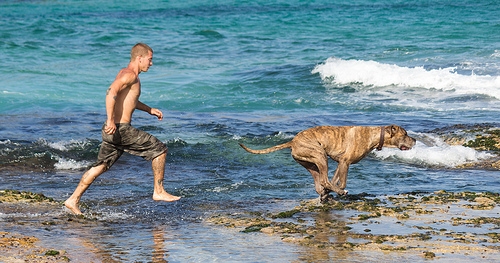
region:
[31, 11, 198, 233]
a man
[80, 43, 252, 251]
a man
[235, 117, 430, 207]
A brindle colored dog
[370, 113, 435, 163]
A dog with a brown collar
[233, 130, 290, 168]
A dog's tail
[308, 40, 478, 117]
An ocean wave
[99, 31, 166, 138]
A shirtless man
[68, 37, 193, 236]
A man running on the water's edge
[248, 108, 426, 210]
A dog running in water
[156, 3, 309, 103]
Blue-green ocean water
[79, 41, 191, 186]
A man wearing shorts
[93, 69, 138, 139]
The arm of a man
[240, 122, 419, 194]
brown and black dog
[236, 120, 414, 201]
dog with brown collar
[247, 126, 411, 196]
dog running in ocean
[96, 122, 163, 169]
green camo swim trunks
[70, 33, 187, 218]
man running on shore line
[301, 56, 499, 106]
wave breaking in ocean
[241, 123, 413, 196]
dog running in sand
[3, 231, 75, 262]
sand along shore line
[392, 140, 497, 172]
white foam in water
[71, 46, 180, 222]
man with no shirt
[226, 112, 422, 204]
the dog running on the water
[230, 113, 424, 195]
the dog running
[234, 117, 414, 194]
the big brown dog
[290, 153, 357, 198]
the dog's four legs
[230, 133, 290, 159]
the dog's brown tail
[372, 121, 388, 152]
the dog's brown collar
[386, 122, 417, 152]
the dog's head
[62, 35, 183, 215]
the man walking in the water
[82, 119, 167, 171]
the man's shorts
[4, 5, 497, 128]
the large body of water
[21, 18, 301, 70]
Water is blue color.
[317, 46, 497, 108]
waves are white color.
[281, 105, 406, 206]
Dog is running in water.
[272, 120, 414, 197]
Dog is brown color.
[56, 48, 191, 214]
One man is chasing the dog.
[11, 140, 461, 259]
Rocks are black color.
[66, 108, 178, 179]
man is wearing grey shorts.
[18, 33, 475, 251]
Day time picture.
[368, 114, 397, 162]
Collar is brown color.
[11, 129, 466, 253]
Rocks are in water.